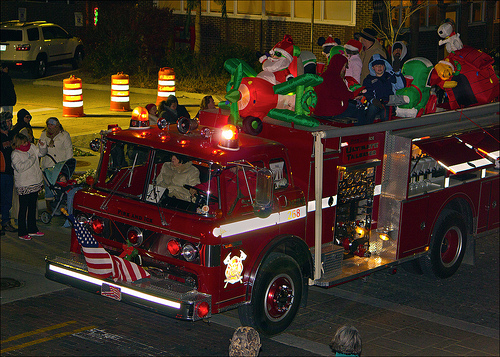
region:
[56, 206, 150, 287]
American flag on front of fire truck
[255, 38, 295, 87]
Inflatable Santa wearing sunglasses on top of truck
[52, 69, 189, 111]
three reflective construction barrels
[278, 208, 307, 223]
numbers on white stripe on side of fire truck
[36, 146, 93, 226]
baby in stroller on left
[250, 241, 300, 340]
front driver side tire of fire truck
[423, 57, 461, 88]
Winnie the Pooh inflatable on top of fire truck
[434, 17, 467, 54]
Snoopy inflatable on top of fire truck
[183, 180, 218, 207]
steering wheel of fire truck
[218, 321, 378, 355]
heads of two spectators shown at the bottom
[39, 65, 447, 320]
A fire engine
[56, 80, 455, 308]
A red fire engine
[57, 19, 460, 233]
A red fire engine at Christmas time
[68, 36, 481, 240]
A red fire engine carrying toys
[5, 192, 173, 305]
An American flag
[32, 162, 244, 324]
An American flag on a red fire engine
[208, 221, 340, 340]
the tire on a fire engine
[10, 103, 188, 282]
people watching the fire engine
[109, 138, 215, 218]
A person driving a fire engine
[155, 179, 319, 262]
A stripe on a fire engine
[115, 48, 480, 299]
red fire truck with Christmas decorations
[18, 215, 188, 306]
American Flag on front of fire truck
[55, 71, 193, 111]
three orange and white cones on fire truck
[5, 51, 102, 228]
people standing on street corner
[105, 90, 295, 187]
lights on top of fire truck turned on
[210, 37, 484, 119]
many Christmas balloons on fire truck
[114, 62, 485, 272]
red fire truck with white stripe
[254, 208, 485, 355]
two tires visible in photograph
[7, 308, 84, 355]
yellow lines in street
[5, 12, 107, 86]
white vehicle parked in background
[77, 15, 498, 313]
fire truck with christmas decorations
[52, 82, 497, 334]
red fire truck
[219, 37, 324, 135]
plush santa figure in a biplane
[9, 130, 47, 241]
woman wearing white coat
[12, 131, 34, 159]
woman wearing red scarf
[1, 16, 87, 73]
white sports utility vehicle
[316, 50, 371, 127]
person wearing red hooded sweatshirt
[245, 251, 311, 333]
tire with red hub cabs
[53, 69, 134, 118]
orange safety cones with white and yellow stripes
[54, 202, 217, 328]
flag mounted on the front of a truck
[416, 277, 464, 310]
part of a road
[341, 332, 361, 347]
part of a hair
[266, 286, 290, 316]
part of a rim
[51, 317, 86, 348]
part of a yellow line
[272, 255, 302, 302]
part of a wheel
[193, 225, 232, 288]
edge of a lorry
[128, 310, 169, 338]
part of a road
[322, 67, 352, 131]
part of a road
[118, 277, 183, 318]
[part of an edge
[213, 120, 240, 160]
part of a lamp